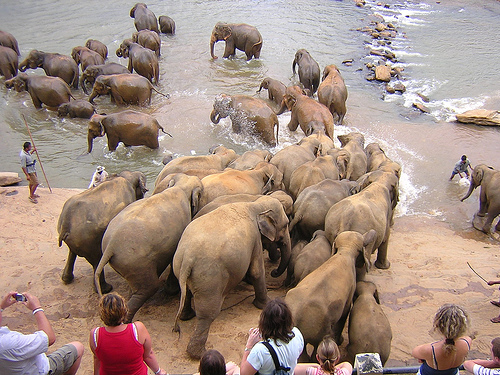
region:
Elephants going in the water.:
[121, 66, 382, 299]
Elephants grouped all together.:
[154, 164, 338, 301]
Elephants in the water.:
[141, 13, 261, 69]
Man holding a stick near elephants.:
[25, 112, 55, 200]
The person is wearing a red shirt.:
[90, 324, 160, 371]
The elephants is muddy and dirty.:
[155, 173, 351, 285]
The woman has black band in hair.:
[438, 309, 460, 347]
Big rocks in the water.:
[360, 33, 399, 98]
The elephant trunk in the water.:
[82, 129, 99, 155]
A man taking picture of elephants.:
[10, 276, 65, 357]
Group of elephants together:
[79, 112, 439, 326]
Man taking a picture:
[10, 283, 80, 373]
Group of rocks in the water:
[357, 14, 429, 106]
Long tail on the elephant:
[88, 243, 126, 318]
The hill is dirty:
[409, 237, 491, 340]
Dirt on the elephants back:
[190, 208, 246, 253]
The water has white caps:
[388, 18, 472, 156]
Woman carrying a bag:
[237, 332, 284, 372]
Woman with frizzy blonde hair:
[416, 293, 459, 351]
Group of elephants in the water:
[14, 20, 200, 177]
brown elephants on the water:
[24, 40, 168, 196]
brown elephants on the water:
[179, 18, 394, 146]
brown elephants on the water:
[44, 24, 215, 150]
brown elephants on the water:
[162, 40, 443, 195]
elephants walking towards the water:
[54, 120, 446, 370]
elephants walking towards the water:
[264, 110, 406, 313]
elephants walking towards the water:
[77, 144, 402, 283]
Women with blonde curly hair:
[427, 302, 473, 362]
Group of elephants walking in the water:
[61, 124, 406, 342]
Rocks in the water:
[351, 1, 438, 125]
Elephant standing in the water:
[203, 18, 265, 67]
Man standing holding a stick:
[8, 106, 63, 211]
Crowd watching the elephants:
[0, 296, 499, 373]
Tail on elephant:
[164, 250, 202, 340]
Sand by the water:
[391, 222, 477, 307]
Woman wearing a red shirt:
[76, 290, 165, 374]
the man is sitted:
[5, 290, 87, 372]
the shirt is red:
[94, 321, 158, 373]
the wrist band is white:
[25, 304, 51, 319]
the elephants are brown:
[135, 175, 380, 287]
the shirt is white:
[245, 341, 312, 372]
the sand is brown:
[405, 249, 466, 313]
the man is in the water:
[450, 151, 477, 186]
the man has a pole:
[15, 132, 55, 199]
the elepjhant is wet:
[85, 110, 163, 152]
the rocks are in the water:
[363, 52, 443, 119]